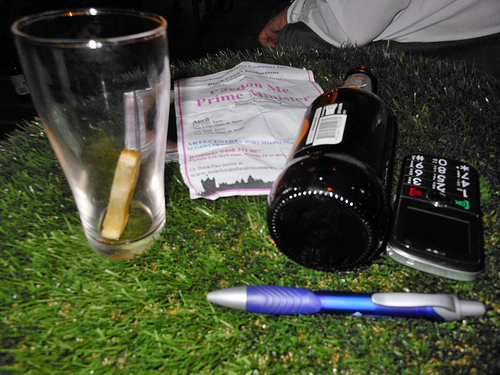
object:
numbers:
[438, 159, 447, 167]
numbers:
[416, 162, 424, 169]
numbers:
[461, 172, 469, 180]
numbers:
[415, 169, 423, 176]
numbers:
[437, 174, 445, 183]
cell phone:
[386, 153, 485, 281]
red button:
[405, 184, 426, 199]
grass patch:
[231, 329, 418, 361]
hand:
[258, 10, 288, 48]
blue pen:
[207, 285, 485, 322]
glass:
[9, 8, 171, 261]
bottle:
[266, 66, 399, 271]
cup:
[11, 8, 172, 258]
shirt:
[285, 0, 497, 49]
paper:
[174, 61, 326, 201]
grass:
[5, 266, 202, 375]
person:
[258, 0, 497, 55]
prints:
[190, 64, 308, 196]